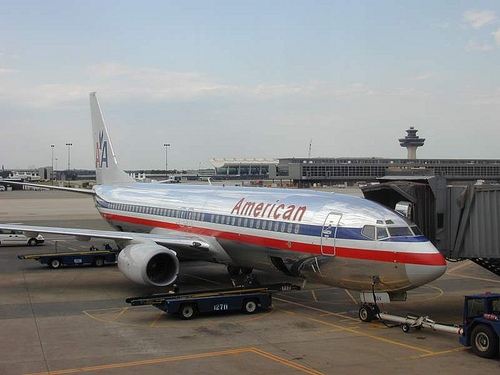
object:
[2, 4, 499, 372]
scene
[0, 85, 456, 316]
plane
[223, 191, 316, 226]
american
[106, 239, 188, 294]
engine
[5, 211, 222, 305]
right side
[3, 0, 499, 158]
sky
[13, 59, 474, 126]
white clouds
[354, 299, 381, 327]
wheels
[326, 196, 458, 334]
front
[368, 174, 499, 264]
tunnel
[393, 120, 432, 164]
signal tower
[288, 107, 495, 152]
distance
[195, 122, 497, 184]
airport terminal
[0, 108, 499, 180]
background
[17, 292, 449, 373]
lines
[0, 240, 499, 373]
pavement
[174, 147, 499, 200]
terminal gate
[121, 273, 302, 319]
cart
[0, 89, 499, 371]
airport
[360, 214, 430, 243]
windows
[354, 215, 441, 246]
cockpit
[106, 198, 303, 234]
windows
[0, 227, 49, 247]
car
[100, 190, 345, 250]
side of plane.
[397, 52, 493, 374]
right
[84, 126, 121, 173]
american airline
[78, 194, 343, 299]
left side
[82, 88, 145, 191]
tail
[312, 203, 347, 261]
door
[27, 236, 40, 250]
wheel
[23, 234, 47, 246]
front side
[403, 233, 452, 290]
nose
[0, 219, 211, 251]
wing